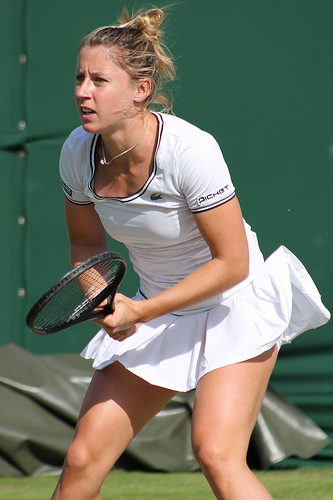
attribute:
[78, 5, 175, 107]
hair — blonde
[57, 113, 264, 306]
shirt — white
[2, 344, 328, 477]
tarp — green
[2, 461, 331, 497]
court — green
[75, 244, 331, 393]
skirt — in the air, tennis skirt, white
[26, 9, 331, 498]
woman — playing tennis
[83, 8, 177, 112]
hair — long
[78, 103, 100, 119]
mouth — open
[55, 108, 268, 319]
shirt — white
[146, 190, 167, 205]
logo — green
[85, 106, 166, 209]
line — maroon